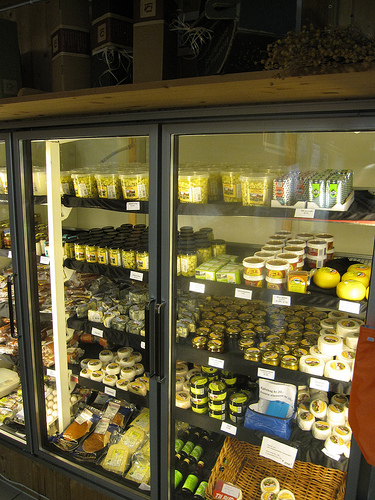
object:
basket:
[205, 436, 348, 499]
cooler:
[0, 104, 374, 500]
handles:
[155, 301, 165, 383]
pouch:
[266, 400, 290, 418]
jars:
[225, 327, 241, 351]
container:
[265, 259, 289, 281]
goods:
[317, 333, 342, 355]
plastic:
[325, 343, 335, 352]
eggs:
[47, 415, 54, 422]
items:
[260, 477, 280, 493]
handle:
[6, 273, 23, 338]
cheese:
[336, 280, 366, 301]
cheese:
[88, 359, 103, 371]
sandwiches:
[83, 433, 104, 453]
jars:
[207, 381, 227, 402]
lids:
[189, 373, 209, 388]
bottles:
[180, 458, 206, 499]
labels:
[182, 474, 199, 492]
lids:
[183, 458, 190, 465]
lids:
[281, 355, 298, 365]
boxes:
[325, 180, 345, 209]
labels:
[275, 187, 284, 197]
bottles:
[180, 251, 197, 277]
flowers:
[258, 25, 374, 77]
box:
[52, 52, 92, 92]